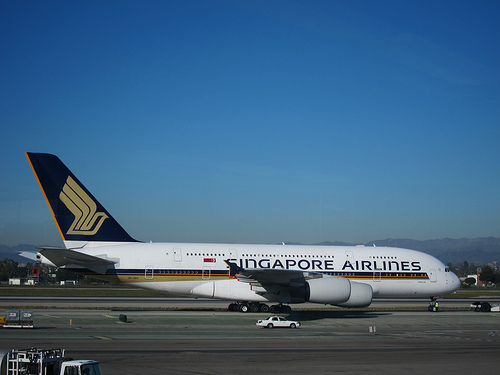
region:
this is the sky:
[158, 21, 403, 163]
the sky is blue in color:
[224, 32, 313, 124]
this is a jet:
[123, 237, 440, 302]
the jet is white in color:
[141, 242, 166, 258]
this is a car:
[257, 312, 303, 330]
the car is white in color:
[276, 319, 284, 324]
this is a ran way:
[160, 346, 293, 373]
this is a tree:
[479, 262, 496, 282]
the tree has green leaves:
[485, 268, 492, 278]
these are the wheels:
[238, 302, 288, 313]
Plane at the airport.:
[8, 154, 419, 346]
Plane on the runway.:
[28, 133, 444, 343]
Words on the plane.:
[152, 175, 442, 330]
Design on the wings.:
[17, 128, 169, 259]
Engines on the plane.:
[184, 241, 384, 369]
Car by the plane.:
[244, 302, 342, 352]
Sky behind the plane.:
[124, 93, 441, 366]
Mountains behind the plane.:
[9, 235, 101, 308]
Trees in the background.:
[382, 202, 497, 297]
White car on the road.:
[216, 290, 345, 363]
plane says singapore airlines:
[25, 159, 474, 354]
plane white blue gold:
[1, 121, 463, 330]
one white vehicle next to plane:
[234, 263, 313, 356]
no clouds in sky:
[11, 71, 490, 336]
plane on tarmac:
[22, 148, 464, 350]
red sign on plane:
[156, 237, 258, 278]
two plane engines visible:
[234, 268, 404, 325]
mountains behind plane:
[4, 223, 490, 311]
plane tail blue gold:
[10, 150, 187, 287]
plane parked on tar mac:
[31, 196, 451, 365]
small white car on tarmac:
[235, 312, 324, 337]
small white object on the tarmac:
[360, 318, 382, 338]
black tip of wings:
[223, 255, 311, 308]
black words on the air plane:
[193, 223, 432, 283]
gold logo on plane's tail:
[47, 171, 139, 235]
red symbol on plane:
[191, 247, 226, 270]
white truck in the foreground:
[13, 343, 116, 373]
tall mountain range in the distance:
[359, 198, 476, 246]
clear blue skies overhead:
[142, 56, 363, 161]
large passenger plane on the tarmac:
[33, 131, 480, 329]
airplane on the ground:
[8, 132, 472, 333]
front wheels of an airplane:
[421, 291, 445, 321]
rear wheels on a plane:
[223, 291, 298, 319]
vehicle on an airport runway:
[249, 308, 307, 339]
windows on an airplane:
[239, 251, 337, 261]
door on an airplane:
[423, 263, 440, 285]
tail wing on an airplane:
[18, 146, 152, 251]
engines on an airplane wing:
[285, 272, 380, 317]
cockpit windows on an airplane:
[439, 262, 456, 278]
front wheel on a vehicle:
[287, 321, 297, 333]